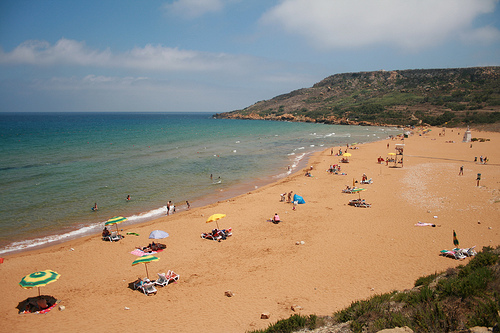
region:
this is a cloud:
[14, 28, 226, 80]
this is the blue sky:
[223, 29, 240, 38]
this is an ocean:
[2, 99, 428, 276]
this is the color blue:
[53, 160, 93, 192]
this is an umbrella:
[6, 263, 81, 315]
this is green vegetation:
[447, 269, 478, 292]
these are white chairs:
[136, 267, 188, 299]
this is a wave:
[16, 217, 136, 251]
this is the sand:
[336, 230, 364, 273]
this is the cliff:
[205, 99, 381, 131]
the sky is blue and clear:
[12, 7, 163, 32]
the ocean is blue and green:
[22, 125, 207, 171]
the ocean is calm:
[20, 140, 195, 180]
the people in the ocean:
[80, 180, 145, 206]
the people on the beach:
[327, 125, 477, 240]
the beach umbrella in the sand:
[20, 256, 66, 311]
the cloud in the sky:
[270, 10, 461, 45]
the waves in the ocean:
[40, 145, 185, 180]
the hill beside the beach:
[217, 65, 485, 125]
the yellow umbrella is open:
[22, 260, 61, 305]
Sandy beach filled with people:
[10, 116, 497, 328]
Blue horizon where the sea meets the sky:
[4, 92, 215, 129]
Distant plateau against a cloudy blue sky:
[322, 55, 496, 129]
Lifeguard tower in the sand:
[391, 133, 409, 170]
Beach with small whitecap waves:
[223, 129, 386, 172]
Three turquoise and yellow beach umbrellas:
[5, 206, 168, 291]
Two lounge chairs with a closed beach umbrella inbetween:
[430, 225, 478, 267]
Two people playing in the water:
[84, 191, 143, 215]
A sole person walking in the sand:
[453, 162, 470, 181]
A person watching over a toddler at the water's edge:
[160, 188, 185, 220]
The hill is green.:
[401, 274, 498, 331]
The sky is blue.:
[18, 3, 193, 43]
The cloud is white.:
[278, 2, 430, 46]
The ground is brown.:
[258, 246, 377, 288]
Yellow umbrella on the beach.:
[201, 207, 230, 228]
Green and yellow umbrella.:
[16, 261, 68, 300]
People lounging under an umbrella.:
[130, 248, 200, 300]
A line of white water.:
[7, 187, 179, 259]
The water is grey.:
[96, 137, 264, 167]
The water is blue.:
[12, 111, 191, 138]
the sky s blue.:
[1, 0, 498, 76]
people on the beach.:
[11, 133, 467, 313]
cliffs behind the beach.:
[230, 56, 493, 131]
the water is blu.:
[3, 107, 288, 204]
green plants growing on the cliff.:
[238, 52, 489, 134]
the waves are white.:
[0, 202, 173, 259]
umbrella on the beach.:
[21, 261, 63, 298]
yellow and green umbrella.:
[17, 267, 60, 290]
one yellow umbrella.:
[203, 202, 230, 228]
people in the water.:
[78, 168, 232, 218]